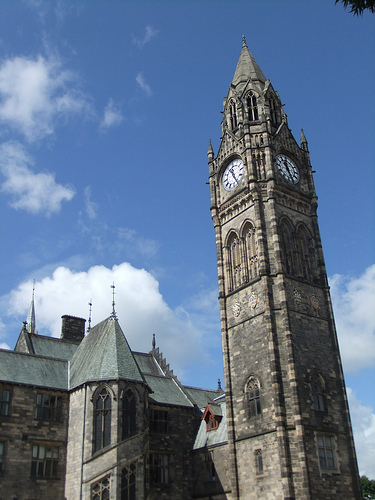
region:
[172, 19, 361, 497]
A large clock tower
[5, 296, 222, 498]
A large church next to the tower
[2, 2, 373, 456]
A clear, blue sky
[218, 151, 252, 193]
A clock on the tower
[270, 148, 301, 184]
A clock on the tower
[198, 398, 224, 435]
A window on the roof of the church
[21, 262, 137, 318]
some spires on the roof of the church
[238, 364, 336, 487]
some windows on the tower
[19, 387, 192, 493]
some windows on the church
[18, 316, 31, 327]
a cross on the roof of the church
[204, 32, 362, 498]
tall stone work clock tower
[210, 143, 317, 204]
two white and black clock faces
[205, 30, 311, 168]
intricate grey stone work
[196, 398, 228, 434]
rust coloured framed window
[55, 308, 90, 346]
grey stone chimney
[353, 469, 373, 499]
leafy green tree top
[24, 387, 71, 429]
eight paned glass window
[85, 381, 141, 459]
two arched windows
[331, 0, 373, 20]
edge of a leafy tree limb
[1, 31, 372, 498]
mostly clear bright blue sky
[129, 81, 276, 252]
a clock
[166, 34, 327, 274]
a clock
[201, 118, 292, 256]
a clock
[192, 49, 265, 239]
a clock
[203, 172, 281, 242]
a clock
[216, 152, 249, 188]
white and black clock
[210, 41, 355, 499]
grey stone clock tower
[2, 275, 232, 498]
grey and brown stone building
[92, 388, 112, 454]
wood window in building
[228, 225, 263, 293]
window in clock tower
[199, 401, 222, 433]
red and grey window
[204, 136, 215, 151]
stone point on tower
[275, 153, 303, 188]
clock in stone tower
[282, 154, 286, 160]
roman numeral number twelve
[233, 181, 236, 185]
roman numeral number six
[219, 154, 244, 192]
clock on tower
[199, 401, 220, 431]
dark red trim on window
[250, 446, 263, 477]
narrow window at bottom of tower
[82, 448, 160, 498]
flower pattern windows on extension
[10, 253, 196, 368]
puffy cloud behind building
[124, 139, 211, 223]
patch of clear blue sky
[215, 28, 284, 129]
pointed room on top of tower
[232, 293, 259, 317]
coats of arms on clock tower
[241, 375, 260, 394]
ornamental arch on tower window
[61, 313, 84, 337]
slender fire chimney on roof